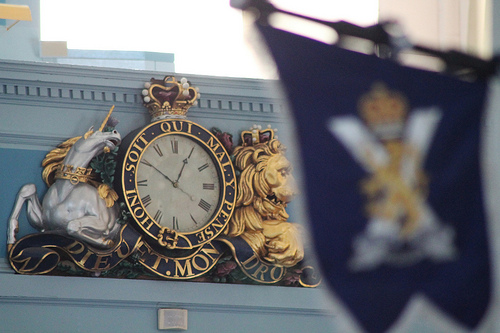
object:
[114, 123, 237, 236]
frame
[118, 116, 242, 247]
clock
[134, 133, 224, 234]
face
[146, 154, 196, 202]
hands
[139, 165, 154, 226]
number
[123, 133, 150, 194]
writing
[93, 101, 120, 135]
horn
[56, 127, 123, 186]
unicorn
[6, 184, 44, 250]
leg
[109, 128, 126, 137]
nose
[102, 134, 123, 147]
mouth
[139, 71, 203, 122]
crowns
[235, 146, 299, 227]
lion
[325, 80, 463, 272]
flag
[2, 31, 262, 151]
buildings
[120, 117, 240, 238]
lettering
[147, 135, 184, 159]
numeral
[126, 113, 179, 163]
roman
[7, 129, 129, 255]
horse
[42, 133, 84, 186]
hair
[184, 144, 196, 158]
numeral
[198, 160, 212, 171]
numeral